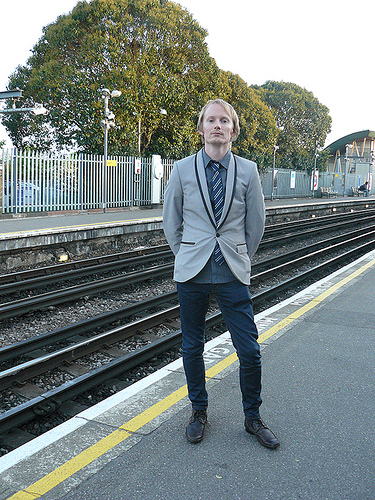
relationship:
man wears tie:
[160, 92, 287, 449] [210, 159, 223, 221]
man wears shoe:
[160, 96, 280, 450] [242, 403, 286, 449]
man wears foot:
[160, 92, 287, 449] [242, 416, 275, 448]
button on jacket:
[216, 231, 219, 236] [161, 145, 266, 286]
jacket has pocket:
[161, 145, 266, 286] [236, 242, 249, 254]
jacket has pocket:
[161, 145, 266, 286] [179, 240, 195, 246]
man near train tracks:
[160, 96, 280, 450] [1, 194, 373, 439]